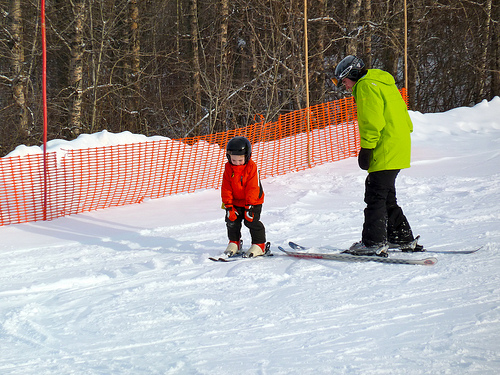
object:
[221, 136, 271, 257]
child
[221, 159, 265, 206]
sweater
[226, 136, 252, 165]
helmet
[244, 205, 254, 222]
glove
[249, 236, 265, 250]
boot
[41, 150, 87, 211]
net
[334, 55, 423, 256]
adult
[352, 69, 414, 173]
jacket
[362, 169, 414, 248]
pants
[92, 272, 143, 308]
snow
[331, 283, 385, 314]
hill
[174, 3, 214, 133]
tree